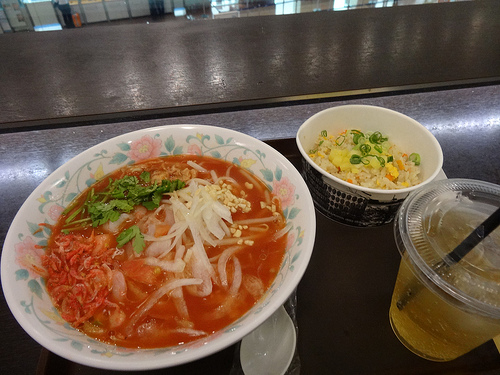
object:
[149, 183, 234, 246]
onion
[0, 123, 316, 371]
dish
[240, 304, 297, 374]
spoon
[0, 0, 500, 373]
table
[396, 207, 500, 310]
straw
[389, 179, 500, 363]
cup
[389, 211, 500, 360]
juice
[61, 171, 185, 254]
coriander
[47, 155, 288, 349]
soup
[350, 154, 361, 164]
pepper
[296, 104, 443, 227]
bowl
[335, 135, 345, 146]
pepper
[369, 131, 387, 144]
pepper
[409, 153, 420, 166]
pepper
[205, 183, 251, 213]
cheese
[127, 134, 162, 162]
flower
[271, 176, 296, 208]
flower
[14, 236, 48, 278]
flower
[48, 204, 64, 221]
flower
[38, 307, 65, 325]
flower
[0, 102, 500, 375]
meal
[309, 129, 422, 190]
rice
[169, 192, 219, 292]
onion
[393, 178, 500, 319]
lid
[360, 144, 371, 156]
scallion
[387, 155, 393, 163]
scallion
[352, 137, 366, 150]
scallion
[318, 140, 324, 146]
scallion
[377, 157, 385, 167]
scallion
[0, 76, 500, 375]
tray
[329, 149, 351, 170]
corn